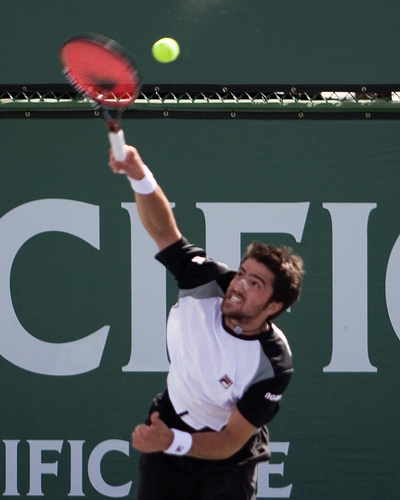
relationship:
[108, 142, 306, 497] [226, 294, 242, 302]
man grit teeth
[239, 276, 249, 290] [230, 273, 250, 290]
breathing strip on nose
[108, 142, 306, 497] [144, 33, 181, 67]
man hit tennis ball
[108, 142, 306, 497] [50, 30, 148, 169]
man hit tennis racket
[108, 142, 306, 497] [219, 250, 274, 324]
man has stubble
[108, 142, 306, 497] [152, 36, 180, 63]
man trying to hit ball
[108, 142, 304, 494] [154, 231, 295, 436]
man wearing tee shirt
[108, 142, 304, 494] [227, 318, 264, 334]
man wearing necklace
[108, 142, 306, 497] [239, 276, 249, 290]
man with breathing strip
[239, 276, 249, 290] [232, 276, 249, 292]
breathing strip on nose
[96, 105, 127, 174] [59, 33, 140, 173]
handle of tennis racket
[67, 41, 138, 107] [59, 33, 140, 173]
strings of tennis racket